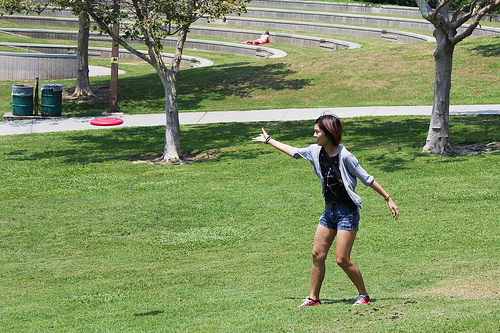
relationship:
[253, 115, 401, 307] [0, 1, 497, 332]
woman in park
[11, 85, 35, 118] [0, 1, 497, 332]
garbage-can in park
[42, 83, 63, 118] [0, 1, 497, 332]
garbage-can in park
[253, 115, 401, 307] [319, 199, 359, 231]
woman wearing shorts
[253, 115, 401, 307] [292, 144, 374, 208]
woman wearing cardigan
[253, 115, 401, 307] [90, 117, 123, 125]
woman playing frisbee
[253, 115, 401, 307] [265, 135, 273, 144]
woman wearing bracelet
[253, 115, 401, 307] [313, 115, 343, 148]
woman has head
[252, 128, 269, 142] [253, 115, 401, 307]
hand of woman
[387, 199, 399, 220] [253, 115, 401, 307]
hand of woman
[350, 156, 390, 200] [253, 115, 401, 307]
arm of woman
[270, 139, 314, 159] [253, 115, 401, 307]
arm of woman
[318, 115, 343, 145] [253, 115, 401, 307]
hair of woman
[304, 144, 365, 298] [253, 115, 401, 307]
body of woman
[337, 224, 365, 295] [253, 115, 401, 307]
leg of woman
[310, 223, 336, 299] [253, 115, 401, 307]
leg of woman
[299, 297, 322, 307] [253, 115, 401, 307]
foot of woman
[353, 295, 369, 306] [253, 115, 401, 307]
foot of woman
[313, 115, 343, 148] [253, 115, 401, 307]
head of woman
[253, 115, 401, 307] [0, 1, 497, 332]
woman at park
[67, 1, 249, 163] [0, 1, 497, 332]
tree in park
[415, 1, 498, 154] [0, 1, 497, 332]
tree in park